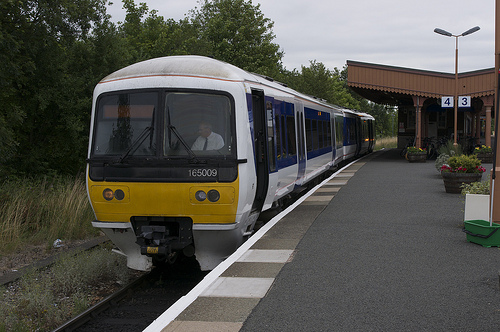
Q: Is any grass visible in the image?
A: Yes, there is grass.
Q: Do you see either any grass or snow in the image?
A: Yes, there is grass.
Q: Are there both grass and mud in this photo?
A: No, there is grass but no mud.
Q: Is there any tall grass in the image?
A: Yes, there is tall grass.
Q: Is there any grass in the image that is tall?
A: Yes, there is grass that is tall.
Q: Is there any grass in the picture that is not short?
A: Yes, there is tall grass.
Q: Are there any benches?
A: No, there are no benches.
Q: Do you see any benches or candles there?
A: No, there are no benches or candles.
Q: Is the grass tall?
A: Yes, the grass is tall.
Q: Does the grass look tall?
A: Yes, the grass is tall.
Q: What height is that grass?
A: The grass is tall.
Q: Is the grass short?
A: No, the grass is tall.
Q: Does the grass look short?
A: No, the grass is tall.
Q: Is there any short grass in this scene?
A: No, there is grass but it is tall.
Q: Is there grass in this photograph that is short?
A: No, there is grass but it is tall.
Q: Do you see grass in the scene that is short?
A: No, there is grass but it is tall.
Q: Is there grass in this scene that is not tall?
A: No, there is grass but it is tall.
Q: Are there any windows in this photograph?
A: Yes, there is a window.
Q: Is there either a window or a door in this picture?
A: Yes, there is a window.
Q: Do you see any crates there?
A: No, there are no crates.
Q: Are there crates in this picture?
A: No, there are no crates.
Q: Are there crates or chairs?
A: No, there are no crates or chairs.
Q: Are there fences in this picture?
A: No, there are no fences.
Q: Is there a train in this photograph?
A: Yes, there is a train.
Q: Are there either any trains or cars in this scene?
A: Yes, there is a train.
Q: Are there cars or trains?
A: Yes, there is a train.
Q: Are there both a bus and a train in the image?
A: No, there is a train but no buses.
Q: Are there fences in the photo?
A: No, there are no fences.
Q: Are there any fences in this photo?
A: No, there are no fences.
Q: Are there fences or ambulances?
A: No, there are no fences or ambulances.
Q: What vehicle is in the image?
A: The vehicle is a train.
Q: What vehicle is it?
A: The vehicle is a train.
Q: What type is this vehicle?
A: This is a train.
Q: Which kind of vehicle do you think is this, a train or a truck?
A: This is a train.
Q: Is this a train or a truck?
A: This is a train.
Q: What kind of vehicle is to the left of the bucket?
A: The vehicle is a train.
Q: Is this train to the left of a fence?
A: No, the train is to the left of a bucket.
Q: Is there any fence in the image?
A: No, there are no fences.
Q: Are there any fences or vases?
A: No, there are no fences or vases.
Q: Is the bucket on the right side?
A: Yes, the bucket is on the right of the image.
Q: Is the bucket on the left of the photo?
A: No, the bucket is on the right of the image.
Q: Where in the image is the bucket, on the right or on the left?
A: The bucket is on the right of the image.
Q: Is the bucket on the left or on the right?
A: The bucket is on the right of the image.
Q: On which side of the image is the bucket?
A: The bucket is on the right of the image.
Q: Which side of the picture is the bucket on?
A: The bucket is on the right of the image.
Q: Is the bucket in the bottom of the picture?
A: Yes, the bucket is in the bottom of the image.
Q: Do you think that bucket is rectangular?
A: Yes, the bucket is rectangular.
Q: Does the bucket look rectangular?
A: Yes, the bucket is rectangular.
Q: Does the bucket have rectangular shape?
A: Yes, the bucket is rectangular.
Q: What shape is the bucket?
A: The bucket is rectangular.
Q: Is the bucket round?
A: No, the bucket is rectangular.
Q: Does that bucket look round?
A: No, the bucket is rectangular.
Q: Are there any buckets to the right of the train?
A: Yes, there is a bucket to the right of the train.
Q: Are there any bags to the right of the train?
A: No, there is a bucket to the right of the train.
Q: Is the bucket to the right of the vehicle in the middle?
A: Yes, the bucket is to the right of the train.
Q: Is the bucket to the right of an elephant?
A: No, the bucket is to the right of the train.